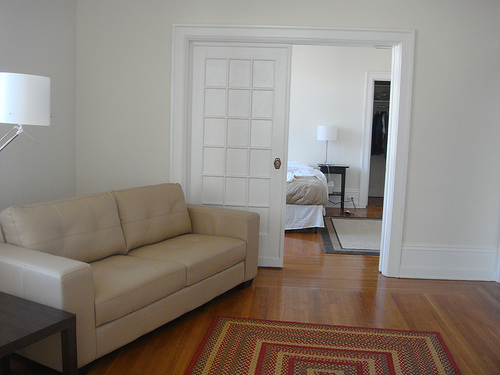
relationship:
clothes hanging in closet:
[368, 109, 391, 155] [366, 68, 436, 244]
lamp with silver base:
[315, 121, 337, 164] [317, 140, 335, 165]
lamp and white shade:
[315, 121, 337, 164] [316, 124, 341, 142]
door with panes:
[187, 38, 291, 270] [203, 57, 273, 142]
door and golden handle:
[187, 38, 291, 270] [267, 152, 284, 176]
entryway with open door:
[163, 15, 409, 284] [196, 51, 293, 278]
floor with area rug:
[208, 271, 429, 372] [188, 303, 457, 372]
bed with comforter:
[288, 164, 329, 234] [286, 178, 322, 204]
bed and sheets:
[288, 164, 329, 234] [290, 205, 327, 234]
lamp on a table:
[315, 118, 336, 164] [324, 165, 348, 216]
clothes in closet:
[368, 109, 391, 155] [361, 72, 395, 217]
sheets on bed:
[287, 165, 319, 227] [283, 146, 345, 223]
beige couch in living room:
[0, 169, 259, 374] [4, 0, 495, 373]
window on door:
[204, 57, 229, 89] [180, 35, 287, 269]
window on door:
[227, 57, 253, 91] [180, 35, 287, 269]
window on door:
[249, 55, 276, 90] [180, 35, 287, 269]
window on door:
[201, 84, 229, 119] [180, 35, 287, 269]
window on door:
[225, 86, 253, 122] [180, 35, 287, 269]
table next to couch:
[0, 291, 79, 373] [0, 181, 262, 373]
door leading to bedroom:
[171, 26, 290, 268] [189, 39, 397, 269]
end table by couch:
[2, 294, 79, 368] [0, 181, 262, 373]